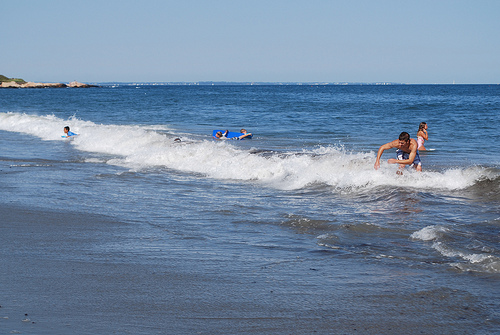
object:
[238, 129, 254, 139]
people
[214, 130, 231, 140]
boy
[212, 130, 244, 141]
surfboard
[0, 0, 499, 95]
sky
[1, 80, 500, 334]
beach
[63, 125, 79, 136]
boy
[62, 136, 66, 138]
surfboard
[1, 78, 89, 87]
sand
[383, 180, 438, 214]
reflection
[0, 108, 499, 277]
wave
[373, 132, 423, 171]
boy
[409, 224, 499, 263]
tiny wave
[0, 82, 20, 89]
rock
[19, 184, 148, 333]
shore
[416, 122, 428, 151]
girl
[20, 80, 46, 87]
rock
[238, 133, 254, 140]
blue clothing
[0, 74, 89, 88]
land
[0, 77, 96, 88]
jetty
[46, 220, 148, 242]
shore line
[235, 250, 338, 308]
shore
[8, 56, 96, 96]
distance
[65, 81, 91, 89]
houses